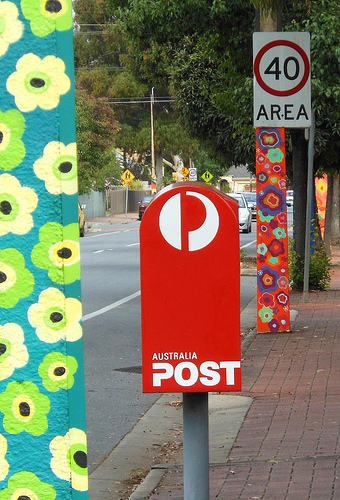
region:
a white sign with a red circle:
[251, 33, 307, 125]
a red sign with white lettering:
[137, 183, 241, 390]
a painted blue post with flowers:
[0, 4, 79, 496]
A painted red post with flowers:
[256, 126, 289, 331]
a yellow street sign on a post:
[119, 165, 135, 218]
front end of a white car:
[229, 193, 252, 230]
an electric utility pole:
[148, 86, 160, 188]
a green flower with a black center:
[29, 220, 79, 284]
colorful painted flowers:
[257, 266, 279, 331]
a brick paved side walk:
[143, 252, 338, 496]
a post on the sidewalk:
[177, 393, 219, 495]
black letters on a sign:
[248, 97, 315, 129]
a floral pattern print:
[42, 428, 95, 489]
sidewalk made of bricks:
[253, 414, 311, 482]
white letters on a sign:
[147, 342, 244, 383]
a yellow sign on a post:
[114, 161, 143, 186]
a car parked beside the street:
[136, 188, 154, 217]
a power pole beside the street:
[141, 82, 166, 141]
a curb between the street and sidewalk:
[119, 458, 173, 495]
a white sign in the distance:
[185, 159, 206, 186]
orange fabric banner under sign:
[254, 125, 288, 332]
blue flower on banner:
[265, 146, 283, 163]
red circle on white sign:
[254, 38, 311, 95]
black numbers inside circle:
[264, 54, 299, 81]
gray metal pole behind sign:
[303, 107, 312, 291]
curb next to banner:
[106, 462, 166, 497]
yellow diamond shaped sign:
[119, 168, 134, 181]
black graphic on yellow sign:
[123, 172, 130, 179]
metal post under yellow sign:
[125, 184, 128, 216]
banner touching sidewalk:
[255, 127, 292, 333]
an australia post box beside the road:
[138, 179, 251, 484]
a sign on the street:
[230, 28, 318, 160]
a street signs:
[116, 160, 215, 182]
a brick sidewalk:
[276, 394, 330, 460]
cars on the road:
[237, 185, 256, 232]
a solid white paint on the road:
[90, 296, 126, 326]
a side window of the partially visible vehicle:
[80, 203, 87, 208]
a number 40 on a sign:
[263, 54, 300, 81]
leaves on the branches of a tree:
[173, 29, 215, 97]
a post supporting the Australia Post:
[169, 396, 235, 498]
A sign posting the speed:
[252, 31, 311, 126]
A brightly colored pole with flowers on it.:
[255, 126, 290, 330]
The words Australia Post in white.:
[144, 350, 241, 385]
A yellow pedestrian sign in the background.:
[117, 168, 135, 185]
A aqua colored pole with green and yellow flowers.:
[1, 2, 88, 499]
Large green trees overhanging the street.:
[73, 34, 338, 194]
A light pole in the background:
[150, 86, 158, 183]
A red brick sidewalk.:
[147, 284, 339, 498]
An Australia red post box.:
[137, 185, 241, 397]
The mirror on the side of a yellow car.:
[79, 202, 86, 208]